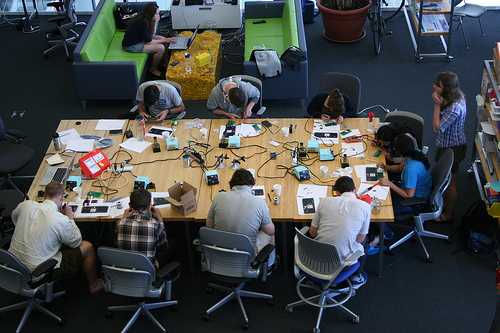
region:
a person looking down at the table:
[18, 38, 219, 124]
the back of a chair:
[96, 240, 153, 298]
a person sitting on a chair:
[110, 175, 184, 303]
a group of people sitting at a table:
[15, 141, 446, 301]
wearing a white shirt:
[308, 193, 378, 256]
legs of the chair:
[101, 301, 191, 331]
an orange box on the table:
[74, 147, 116, 182]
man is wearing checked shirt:
[111, 204, 180, 279]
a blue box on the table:
[220, 129, 244, 152]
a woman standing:
[424, 58, 486, 168]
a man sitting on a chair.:
[181, 159, 289, 331]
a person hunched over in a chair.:
[286, 160, 394, 325]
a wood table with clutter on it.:
[20, 108, 392, 248]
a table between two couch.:
[144, 22, 234, 94]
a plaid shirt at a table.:
[81, 177, 177, 331]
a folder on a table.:
[67, 143, 122, 189]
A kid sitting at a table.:
[371, 112, 472, 269]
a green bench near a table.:
[247, 5, 317, 73]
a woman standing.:
[401, 60, 481, 230]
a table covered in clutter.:
[0, 100, 392, 256]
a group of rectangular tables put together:
[23, 113, 396, 277]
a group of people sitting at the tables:
[11, 78, 436, 289]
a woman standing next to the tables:
[430, 68, 467, 223]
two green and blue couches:
[71, 0, 308, 110]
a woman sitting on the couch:
[121, 4, 178, 75]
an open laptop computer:
[168, 24, 200, 50]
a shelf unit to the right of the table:
[466, 42, 498, 224]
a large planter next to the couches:
[315, 0, 372, 43]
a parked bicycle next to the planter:
[368, 0, 405, 57]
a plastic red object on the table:
[78, 148, 110, 177]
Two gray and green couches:
[70, 1, 312, 108]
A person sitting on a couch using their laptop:
[120, 2, 197, 80]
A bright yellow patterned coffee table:
[167, 26, 224, 102]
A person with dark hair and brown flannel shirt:
[114, 188, 181, 290]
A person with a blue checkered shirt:
[430, 71, 469, 225]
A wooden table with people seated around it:
[0, 66, 456, 331]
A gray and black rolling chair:
[188, 223, 276, 330]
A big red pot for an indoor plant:
[315, 0, 372, 45]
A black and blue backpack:
[449, 200, 495, 262]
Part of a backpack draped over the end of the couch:
[248, 46, 283, 80]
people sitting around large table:
[22, 65, 457, 311]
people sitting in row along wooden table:
[15, 161, 414, 307]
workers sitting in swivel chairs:
[200, 167, 397, 324]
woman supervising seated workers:
[301, 43, 498, 295]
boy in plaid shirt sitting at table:
[101, 185, 175, 305]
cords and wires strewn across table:
[59, 111, 361, 204]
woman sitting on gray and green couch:
[77, 3, 203, 90]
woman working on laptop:
[123, 6, 216, 66]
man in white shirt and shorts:
[10, 182, 95, 292]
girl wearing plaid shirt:
[428, 72, 470, 221]